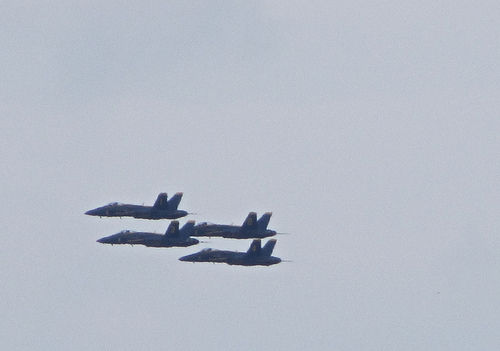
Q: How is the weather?
A: It is cloudless.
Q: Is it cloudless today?
A: Yes, it is cloudless.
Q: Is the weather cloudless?
A: Yes, it is cloudless.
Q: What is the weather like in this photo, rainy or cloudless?
A: It is cloudless.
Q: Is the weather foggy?
A: No, it is cloudless.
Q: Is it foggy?
A: No, it is cloudless.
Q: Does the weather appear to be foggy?
A: No, it is cloudless.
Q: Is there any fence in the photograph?
A: No, there are no fences.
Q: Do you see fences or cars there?
A: No, there are no fences or cars.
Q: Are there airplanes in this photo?
A: Yes, there is an airplane.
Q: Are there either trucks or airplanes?
A: Yes, there is an airplane.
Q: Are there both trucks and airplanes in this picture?
A: No, there is an airplane but no trucks.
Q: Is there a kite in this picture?
A: No, there are no kites.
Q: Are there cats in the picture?
A: No, there are no cats.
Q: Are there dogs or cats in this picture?
A: No, there are no cats or dogs.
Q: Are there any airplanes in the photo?
A: Yes, there are airplanes.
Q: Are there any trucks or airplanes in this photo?
A: Yes, there are airplanes.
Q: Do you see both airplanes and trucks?
A: No, there are airplanes but no trucks.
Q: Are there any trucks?
A: No, there are no trucks.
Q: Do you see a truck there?
A: No, there are no trucks.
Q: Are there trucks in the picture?
A: No, there are no trucks.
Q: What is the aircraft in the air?
A: The aircraft is airplanes.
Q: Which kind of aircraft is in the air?
A: The aircraft is airplanes.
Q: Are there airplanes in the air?
A: Yes, there are airplanes in the air.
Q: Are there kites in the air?
A: No, there are airplanes in the air.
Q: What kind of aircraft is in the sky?
A: The aircraft is airplanes.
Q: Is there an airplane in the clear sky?
A: Yes, there are airplanes in the sky.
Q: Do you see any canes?
A: No, there are no canes.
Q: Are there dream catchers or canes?
A: No, there are no canes or dream catchers.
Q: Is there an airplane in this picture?
A: Yes, there are airplanes.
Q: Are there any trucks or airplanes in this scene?
A: Yes, there are airplanes.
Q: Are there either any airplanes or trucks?
A: Yes, there are airplanes.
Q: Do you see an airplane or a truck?
A: Yes, there are airplanes.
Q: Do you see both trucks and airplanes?
A: No, there are airplanes but no trucks.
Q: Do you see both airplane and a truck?
A: No, there are airplanes but no trucks.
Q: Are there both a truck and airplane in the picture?
A: No, there are airplanes but no trucks.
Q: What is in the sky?
A: The airplanes are in the sky.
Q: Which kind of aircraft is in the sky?
A: The aircraft is airplanes.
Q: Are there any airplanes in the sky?
A: Yes, there are airplanes in the sky.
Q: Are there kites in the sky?
A: No, there are airplanes in the sky.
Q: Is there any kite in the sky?
A: No, there are airplanes in the sky.